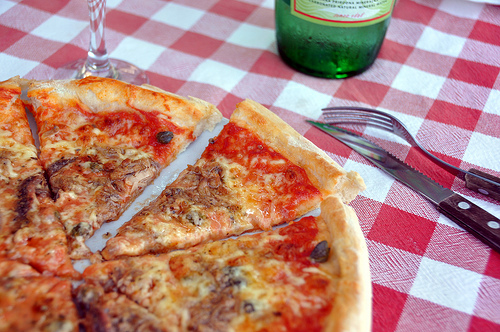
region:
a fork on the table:
[320, 103, 499, 195]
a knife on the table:
[308, 114, 498, 258]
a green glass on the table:
[272, 0, 388, 72]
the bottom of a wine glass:
[53, 0, 143, 88]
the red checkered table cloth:
[157, 8, 254, 87]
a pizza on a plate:
[1, 73, 353, 330]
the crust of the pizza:
[35, 78, 206, 123]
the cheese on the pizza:
[54, 117, 90, 133]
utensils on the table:
[314, 98, 483, 245]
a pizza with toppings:
[8, 76, 360, 329]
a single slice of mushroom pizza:
[103, 95, 353, 255]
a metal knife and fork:
[310, 95, 498, 256]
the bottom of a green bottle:
[276, 0, 400, 77]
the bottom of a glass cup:
[56, 0, 144, 87]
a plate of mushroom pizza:
[0, 59, 400, 327]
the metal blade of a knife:
[311, 120, 456, 204]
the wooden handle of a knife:
[439, 191, 497, 247]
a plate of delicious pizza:
[0, 59, 382, 329]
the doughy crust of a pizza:
[320, 198, 373, 330]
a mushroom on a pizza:
[16, 173, 43, 223]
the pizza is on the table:
[12, 60, 369, 329]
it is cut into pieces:
[7, 70, 373, 330]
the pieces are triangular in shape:
[89, 108, 364, 278]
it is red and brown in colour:
[1, 55, 354, 329]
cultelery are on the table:
[299, 89, 496, 198]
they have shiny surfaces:
[303, 93, 451, 188]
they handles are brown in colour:
[428, 158, 495, 233]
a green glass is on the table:
[266, 0, 399, 69]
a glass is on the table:
[56, 0, 148, 75]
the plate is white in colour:
[98, 117, 185, 243]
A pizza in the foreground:
[0, 48, 379, 329]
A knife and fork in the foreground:
[306, 85, 498, 256]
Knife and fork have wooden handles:
[423, 160, 498, 255]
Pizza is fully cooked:
[5, 58, 374, 330]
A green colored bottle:
[261, 3, 405, 93]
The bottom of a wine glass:
[43, 0, 148, 90]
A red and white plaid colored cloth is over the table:
[2, 0, 494, 324]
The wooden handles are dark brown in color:
[427, 153, 497, 253]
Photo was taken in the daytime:
[5, 0, 491, 327]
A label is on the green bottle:
[288, 0, 395, 36]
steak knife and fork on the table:
[293, 90, 496, 250]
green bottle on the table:
[262, 2, 399, 77]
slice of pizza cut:
[26, 48, 202, 248]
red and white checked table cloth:
[411, 17, 470, 139]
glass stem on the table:
[56, 11, 142, 84]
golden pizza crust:
[30, 68, 205, 118]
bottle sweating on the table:
[271, 23, 388, 78]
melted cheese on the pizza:
[231, 165, 259, 205]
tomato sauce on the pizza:
[219, 130, 280, 207]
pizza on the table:
[3, 103, 259, 321]